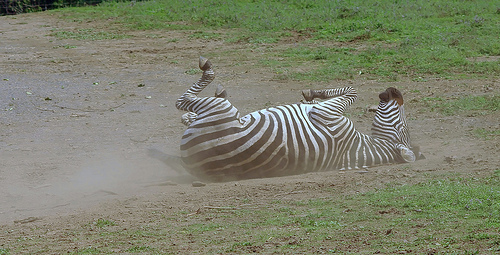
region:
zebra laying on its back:
[152, 10, 442, 212]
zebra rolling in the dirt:
[130, 30, 492, 208]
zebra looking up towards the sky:
[114, 32, 476, 229]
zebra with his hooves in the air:
[135, 22, 499, 176]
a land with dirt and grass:
[47, 11, 483, 231]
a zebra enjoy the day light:
[89, 17, 419, 254]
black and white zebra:
[126, 35, 488, 249]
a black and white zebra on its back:
[141, 32, 466, 209]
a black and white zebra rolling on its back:
[145, 21, 458, 213]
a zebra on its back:
[165, 50, 437, 195]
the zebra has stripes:
[220, 117, 310, 161]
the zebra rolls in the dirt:
[141, 49, 440, 198]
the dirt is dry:
[12, 127, 180, 214]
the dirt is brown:
[8, 125, 175, 206]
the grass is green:
[107, 0, 494, 34]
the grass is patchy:
[63, 9, 455, 81]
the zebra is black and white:
[189, 60, 437, 179]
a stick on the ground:
[187, 197, 277, 222]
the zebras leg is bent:
[175, 50, 233, 138]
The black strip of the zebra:
[193, 117, 229, 125]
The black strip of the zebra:
[183, 127, 245, 143]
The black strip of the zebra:
[246, 108, 264, 151]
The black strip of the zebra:
[182, 151, 222, 166]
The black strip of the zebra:
[271, 119, 282, 151]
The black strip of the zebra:
[288, 110, 303, 147]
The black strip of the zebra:
[284, 112, 291, 154]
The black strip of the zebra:
[297, 110, 311, 147]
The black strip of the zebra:
[318, 137, 326, 172]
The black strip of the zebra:
[308, 147, 313, 166]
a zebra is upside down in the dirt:
[136, 55, 428, 183]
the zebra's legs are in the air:
[172, 47, 422, 173]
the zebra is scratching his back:
[133, 46, 426, 187]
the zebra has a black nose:
[375, 81, 405, 101]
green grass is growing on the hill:
[15, 3, 493, 246]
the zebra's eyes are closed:
[395, 115, 420, 156]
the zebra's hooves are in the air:
[192, 46, 318, 103]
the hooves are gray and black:
[193, 51, 321, 106]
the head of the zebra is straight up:
[365, 80, 421, 166]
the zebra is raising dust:
[13, 59, 445, 202]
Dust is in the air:
[20, 107, 233, 199]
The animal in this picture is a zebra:
[158, 34, 435, 199]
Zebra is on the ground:
[146, 41, 440, 197]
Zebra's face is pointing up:
[370, 73, 429, 179]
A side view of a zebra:
[129, 21, 454, 195]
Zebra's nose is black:
[368, 80, 403, 110]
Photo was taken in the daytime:
[21, 12, 498, 247]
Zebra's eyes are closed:
[389, 115, 409, 145]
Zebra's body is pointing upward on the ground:
[157, 45, 452, 204]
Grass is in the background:
[207, 8, 492, 56]